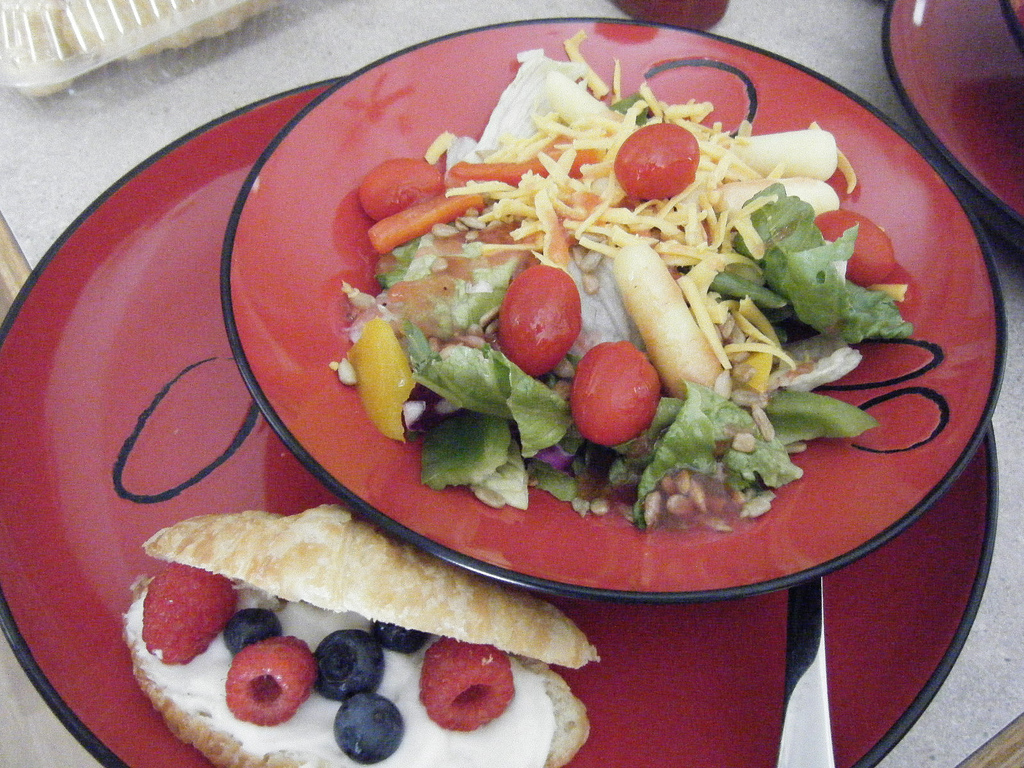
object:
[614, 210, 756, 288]
cheese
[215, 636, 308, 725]
raspberry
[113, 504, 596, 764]
tart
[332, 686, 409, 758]
blueberries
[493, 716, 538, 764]
cream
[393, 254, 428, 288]
pepper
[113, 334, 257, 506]
design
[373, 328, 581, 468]
lettuce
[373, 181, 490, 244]
carrot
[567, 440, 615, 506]
olive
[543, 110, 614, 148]
cheese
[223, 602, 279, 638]
olives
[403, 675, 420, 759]
cream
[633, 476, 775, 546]
salad dressing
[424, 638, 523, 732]
raspberries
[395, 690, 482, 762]
cream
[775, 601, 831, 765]
utensil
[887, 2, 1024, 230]
plate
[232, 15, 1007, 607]
bowl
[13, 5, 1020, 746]
counter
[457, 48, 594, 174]
lettuce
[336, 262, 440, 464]
food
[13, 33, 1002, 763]
plates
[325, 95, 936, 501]
food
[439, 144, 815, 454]
salad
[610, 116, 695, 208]
tomato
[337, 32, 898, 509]
salad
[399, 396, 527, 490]
lettuce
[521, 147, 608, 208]
cheese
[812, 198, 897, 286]
tomato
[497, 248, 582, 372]
tomato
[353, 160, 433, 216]
tomato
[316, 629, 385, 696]
blueberry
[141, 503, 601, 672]
bread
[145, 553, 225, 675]
raspberry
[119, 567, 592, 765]
bread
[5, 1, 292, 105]
container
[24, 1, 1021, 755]
table